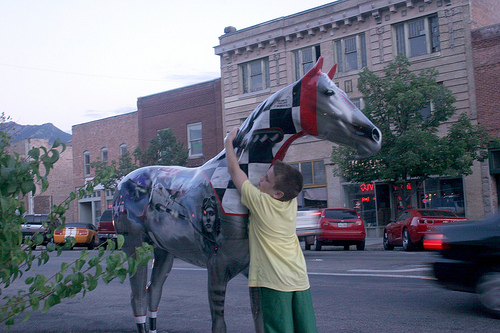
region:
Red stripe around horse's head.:
[300, 62, 322, 140]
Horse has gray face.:
[329, 103, 394, 158]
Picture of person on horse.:
[190, 191, 222, 253]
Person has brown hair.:
[265, 156, 302, 213]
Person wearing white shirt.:
[246, 209, 305, 264]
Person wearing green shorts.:
[248, 295, 313, 325]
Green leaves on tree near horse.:
[52, 250, 142, 302]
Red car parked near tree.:
[385, 203, 435, 264]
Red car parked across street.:
[310, 190, 361, 269]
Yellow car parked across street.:
[53, 224, 104, 263]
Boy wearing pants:
[245, 278, 322, 329]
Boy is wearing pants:
[246, 273, 317, 329]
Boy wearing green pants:
[259, 278, 321, 331]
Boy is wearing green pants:
[252, 279, 327, 331]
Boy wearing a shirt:
[240, 178, 315, 291]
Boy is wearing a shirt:
[235, 175, 315, 291]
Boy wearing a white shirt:
[240, 176, 312, 288]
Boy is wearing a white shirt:
[237, 178, 319, 294]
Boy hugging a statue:
[217, 118, 329, 331]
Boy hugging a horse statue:
[222, 120, 323, 331]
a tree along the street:
[336, 65, 468, 230]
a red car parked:
[312, 208, 370, 245]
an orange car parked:
[53, 223, 95, 241]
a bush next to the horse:
[1, 135, 143, 325]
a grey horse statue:
[104, 65, 384, 320]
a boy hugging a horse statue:
[223, 131, 333, 331]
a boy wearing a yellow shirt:
[229, 137, 331, 324]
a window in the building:
[240, 55, 269, 93]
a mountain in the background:
[6, 114, 72, 147]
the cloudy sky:
[4, 18, 204, 74]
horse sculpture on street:
[118, 56, 380, 331]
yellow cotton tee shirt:
[240, 180, 310, 290]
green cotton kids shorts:
[248, 284, 316, 331]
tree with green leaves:
[331, 58, 481, 227]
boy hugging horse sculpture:
[222, 128, 314, 332]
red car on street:
[384, 205, 465, 250]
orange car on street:
[53, 222, 96, 245]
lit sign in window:
[357, 182, 374, 192]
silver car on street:
[19, 211, 54, 240]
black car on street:
[426, 212, 498, 315]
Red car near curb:
[312, 202, 368, 251]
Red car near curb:
[379, 203, 465, 252]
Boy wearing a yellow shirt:
[217, 130, 334, 332]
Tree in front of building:
[328, 55, 492, 236]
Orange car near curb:
[49, 209, 102, 251]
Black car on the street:
[415, 203, 499, 312]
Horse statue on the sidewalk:
[77, 50, 399, 330]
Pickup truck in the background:
[11, 205, 64, 247]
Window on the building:
[228, 52, 288, 98]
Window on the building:
[174, 115, 212, 170]